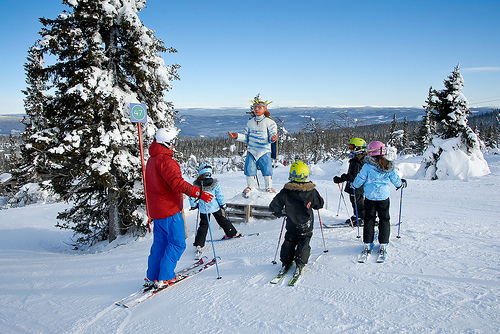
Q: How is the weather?
A: It is clear.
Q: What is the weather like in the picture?
A: It is clear.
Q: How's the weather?
A: It is clear.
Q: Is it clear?
A: Yes, it is clear.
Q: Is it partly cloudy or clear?
A: It is clear.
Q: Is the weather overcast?
A: No, it is clear.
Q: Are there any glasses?
A: No, there are no glasses.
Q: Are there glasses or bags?
A: No, there are no glasses or bags.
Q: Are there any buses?
A: No, there are no buses.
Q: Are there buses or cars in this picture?
A: No, there are no buses or cars.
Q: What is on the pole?
A: The sign is on the pole.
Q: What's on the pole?
A: The sign is on the pole.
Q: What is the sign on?
A: The sign is on the pole.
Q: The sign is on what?
A: The sign is on the pole.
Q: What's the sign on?
A: The sign is on the pole.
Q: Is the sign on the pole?
A: Yes, the sign is on the pole.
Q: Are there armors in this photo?
A: No, there are no armors.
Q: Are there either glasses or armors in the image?
A: No, there are no armors or glasses.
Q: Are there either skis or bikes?
A: Yes, there are skis.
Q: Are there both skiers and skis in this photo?
A: Yes, there are both skis and a skier.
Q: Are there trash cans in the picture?
A: No, there are no trash cans.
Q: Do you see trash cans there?
A: No, there are no trash cans.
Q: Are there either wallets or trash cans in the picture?
A: No, there are no trash cans or wallets.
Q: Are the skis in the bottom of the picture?
A: Yes, the skis are in the bottom of the image.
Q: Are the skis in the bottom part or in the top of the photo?
A: The skis are in the bottom of the image.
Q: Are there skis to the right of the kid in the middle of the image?
A: Yes, there are skis to the right of the kid.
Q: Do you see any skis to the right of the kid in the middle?
A: Yes, there are skis to the right of the kid.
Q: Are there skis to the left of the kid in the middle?
A: No, the skis are to the right of the child.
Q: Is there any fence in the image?
A: No, there are no fences.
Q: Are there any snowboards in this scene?
A: No, there are no snowboards.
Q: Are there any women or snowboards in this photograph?
A: No, there are no snowboards or women.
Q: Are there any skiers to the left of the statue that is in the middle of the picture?
A: Yes, there is a skier to the left of the statue.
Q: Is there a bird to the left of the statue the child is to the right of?
A: No, there is a skier to the left of the statue.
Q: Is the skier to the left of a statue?
A: Yes, the skier is to the left of a statue.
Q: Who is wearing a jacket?
A: The skier is wearing a jacket.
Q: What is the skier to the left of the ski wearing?
A: The skier is wearing a jacket.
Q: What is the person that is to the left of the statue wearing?
A: The skier is wearing a jacket.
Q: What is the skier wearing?
A: The skier is wearing a jacket.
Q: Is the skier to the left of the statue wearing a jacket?
A: Yes, the skier is wearing a jacket.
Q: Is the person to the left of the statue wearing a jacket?
A: Yes, the skier is wearing a jacket.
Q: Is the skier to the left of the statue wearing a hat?
A: No, the skier is wearing a jacket.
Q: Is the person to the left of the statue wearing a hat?
A: No, the skier is wearing a jacket.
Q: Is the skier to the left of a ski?
A: Yes, the skier is to the left of a ski.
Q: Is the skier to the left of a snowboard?
A: No, the skier is to the left of a ski.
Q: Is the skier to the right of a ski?
A: No, the skier is to the left of a ski.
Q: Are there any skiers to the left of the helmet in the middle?
A: Yes, there is a skier to the left of the helmet.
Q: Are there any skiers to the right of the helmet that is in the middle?
A: No, the skier is to the left of the helmet.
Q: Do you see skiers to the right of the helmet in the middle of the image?
A: No, the skier is to the left of the helmet.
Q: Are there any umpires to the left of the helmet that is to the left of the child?
A: No, there is a skier to the left of the helmet.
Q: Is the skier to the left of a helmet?
A: Yes, the skier is to the left of a helmet.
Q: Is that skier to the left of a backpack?
A: No, the skier is to the left of a helmet.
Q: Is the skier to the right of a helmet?
A: No, the skier is to the left of a helmet.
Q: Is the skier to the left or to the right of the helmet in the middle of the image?
A: The skier is to the left of the helmet.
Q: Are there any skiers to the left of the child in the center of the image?
A: Yes, there is a skier to the left of the kid.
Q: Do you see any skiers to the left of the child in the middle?
A: Yes, there is a skier to the left of the kid.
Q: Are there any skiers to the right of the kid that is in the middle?
A: No, the skier is to the left of the child.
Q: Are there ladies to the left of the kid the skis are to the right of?
A: No, there is a skier to the left of the kid.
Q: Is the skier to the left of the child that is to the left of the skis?
A: Yes, the skier is to the left of the kid.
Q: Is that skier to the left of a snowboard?
A: No, the skier is to the left of the kid.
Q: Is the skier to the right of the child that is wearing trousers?
A: No, the skier is to the left of the kid.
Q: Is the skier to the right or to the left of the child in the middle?
A: The skier is to the left of the kid.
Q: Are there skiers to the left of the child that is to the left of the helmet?
A: Yes, there is a skier to the left of the kid.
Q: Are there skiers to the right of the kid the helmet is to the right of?
A: No, the skier is to the left of the kid.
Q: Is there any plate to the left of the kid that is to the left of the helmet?
A: No, there is a skier to the left of the kid.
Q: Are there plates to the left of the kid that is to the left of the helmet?
A: No, there is a skier to the left of the kid.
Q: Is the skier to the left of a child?
A: Yes, the skier is to the left of a child.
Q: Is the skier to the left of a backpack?
A: No, the skier is to the left of a child.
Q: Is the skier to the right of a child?
A: No, the skier is to the left of a child.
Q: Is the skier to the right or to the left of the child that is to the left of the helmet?
A: The skier is to the left of the child.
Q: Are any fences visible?
A: No, there are no fences.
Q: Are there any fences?
A: No, there are no fences.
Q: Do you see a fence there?
A: No, there are no fences.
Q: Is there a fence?
A: No, there are no fences.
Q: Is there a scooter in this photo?
A: No, there are no scooters.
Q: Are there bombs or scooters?
A: No, there are no scooters or bombs.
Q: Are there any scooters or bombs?
A: No, there are no scooters or bombs.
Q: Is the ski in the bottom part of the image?
A: Yes, the ski is in the bottom of the image.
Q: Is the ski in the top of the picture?
A: No, the ski is in the bottom of the image.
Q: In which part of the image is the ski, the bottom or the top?
A: The ski is in the bottom of the image.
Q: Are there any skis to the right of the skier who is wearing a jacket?
A: Yes, there is a ski to the right of the skier.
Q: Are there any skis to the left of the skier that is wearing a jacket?
A: No, the ski is to the right of the skier.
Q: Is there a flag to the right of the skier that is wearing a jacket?
A: No, there is a ski to the right of the skier.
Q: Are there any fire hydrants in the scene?
A: No, there are no fire hydrants.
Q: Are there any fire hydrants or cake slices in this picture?
A: No, there are no fire hydrants or cake slices.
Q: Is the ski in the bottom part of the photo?
A: Yes, the ski is in the bottom of the image.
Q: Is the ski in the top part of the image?
A: No, the ski is in the bottom of the image.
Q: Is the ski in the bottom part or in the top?
A: The ski is in the bottom of the image.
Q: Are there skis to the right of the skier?
A: Yes, there is a ski to the right of the skier.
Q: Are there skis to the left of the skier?
A: No, the ski is to the right of the skier.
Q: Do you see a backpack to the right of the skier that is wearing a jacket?
A: No, there is a ski to the right of the skier.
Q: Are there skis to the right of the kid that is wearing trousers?
A: Yes, there is a ski to the right of the kid.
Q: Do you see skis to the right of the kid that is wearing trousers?
A: Yes, there is a ski to the right of the kid.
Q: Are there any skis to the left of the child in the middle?
A: No, the ski is to the right of the kid.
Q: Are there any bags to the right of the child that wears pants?
A: No, there is a ski to the right of the kid.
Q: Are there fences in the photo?
A: No, there are no fences.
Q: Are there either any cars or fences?
A: No, there are no fences or cars.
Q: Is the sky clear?
A: Yes, the sky is clear.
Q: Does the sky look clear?
A: Yes, the sky is clear.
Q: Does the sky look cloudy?
A: No, the sky is clear.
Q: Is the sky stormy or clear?
A: The sky is clear.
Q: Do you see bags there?
A: No, there are no bags.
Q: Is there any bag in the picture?
A: No, there are no bags.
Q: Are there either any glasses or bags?
A: No, there are no bags or glasses.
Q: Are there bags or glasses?
A: No, there are no bags or glasses.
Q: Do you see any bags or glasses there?
A: No, there are no bags or glasses.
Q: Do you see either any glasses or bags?
A: No, there are no bags or glasses.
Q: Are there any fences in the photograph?
A: No, there are no fences.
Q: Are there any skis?
A: Yes, there are skis.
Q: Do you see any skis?
A: Yes, there are skis.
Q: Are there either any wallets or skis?
A: Yes, there are skis.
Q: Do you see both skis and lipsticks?
A: No, there are skis but no lipsticks.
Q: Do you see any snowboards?
A: No, there are no snowboards.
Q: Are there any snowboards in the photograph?
A: No, there are no snowboards.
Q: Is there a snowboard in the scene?
A: No, there are no snowboards.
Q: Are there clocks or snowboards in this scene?
A: No, there are no snowboards or clocks.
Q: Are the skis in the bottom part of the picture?
A: Yes, the skis are in the bottom of the image.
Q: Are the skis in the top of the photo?
A: No, the skis are in the bottom of the image.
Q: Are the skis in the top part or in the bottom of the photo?
A: The skis are in the bottom of the image.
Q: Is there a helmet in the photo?
A: Yes, there is a helmet.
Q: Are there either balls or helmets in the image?
A: Yes, there is a helmet.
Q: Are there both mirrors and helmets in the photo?
A: No, there is a helmet but no mirrors.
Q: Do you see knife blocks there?
A: No, there are no knife blocks.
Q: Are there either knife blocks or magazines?
A: No, there are no knife blocks or magazines.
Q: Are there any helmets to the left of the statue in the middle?
A: Yes, there is a helmet to the left of the statue.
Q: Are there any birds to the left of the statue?
A: No, there is a helmet to the left of the statue.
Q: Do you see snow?
A: Yes, there is snow.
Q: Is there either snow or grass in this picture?
A: Yes, there is snow.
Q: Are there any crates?
A: No, there are no crates.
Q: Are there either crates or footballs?
A: No, there are no crates or footballs.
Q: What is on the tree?
A: The snow is on the tree.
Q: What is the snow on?
A: The snow is on the tree.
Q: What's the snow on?
A: The snow is on the tree.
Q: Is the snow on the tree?
A: Yes, the snow is on the tree.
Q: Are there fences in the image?
A: No, there are no fences.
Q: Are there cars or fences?
A: No, there are no fences or cars.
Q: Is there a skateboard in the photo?
A: No, there are no skateboards.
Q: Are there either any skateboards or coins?
A: No, there are no skateboards or coins.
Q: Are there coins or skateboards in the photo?
A: No, there are no skateboards or coins.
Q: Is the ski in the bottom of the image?
A: Yes, the ski is in the bottom of the image.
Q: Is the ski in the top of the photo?
A: No, the ski is in the bottom of the image.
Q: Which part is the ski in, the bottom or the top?
A: The ski is in the bottom of the image.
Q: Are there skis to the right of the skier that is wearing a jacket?
A: Yes, there is a ski to the right of the skier.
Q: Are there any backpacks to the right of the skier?
A: No, there is a ski to the right of the skier.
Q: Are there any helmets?
A: Yes, there is a helmet.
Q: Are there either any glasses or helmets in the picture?
A: Yes, there is a helmet.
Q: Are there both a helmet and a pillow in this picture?
A: No, there is a helmet but no pillows.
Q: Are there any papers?
A: No, there are no papers.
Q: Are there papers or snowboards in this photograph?
A: No, there are no papers or snowboards.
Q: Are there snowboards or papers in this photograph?
A: No, there are no papers or snowboards.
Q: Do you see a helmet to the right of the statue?
A: Yes, there is a helmet to the right of the statue.